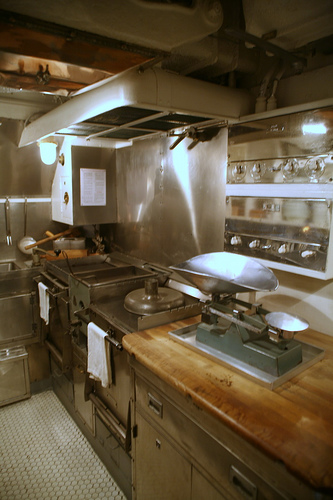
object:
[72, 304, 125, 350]
rack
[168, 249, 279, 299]
bed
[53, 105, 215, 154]
range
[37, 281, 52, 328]
towel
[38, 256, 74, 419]
stove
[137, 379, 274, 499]
drawer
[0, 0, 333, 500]
kitchen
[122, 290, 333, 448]
counter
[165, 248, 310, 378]
scale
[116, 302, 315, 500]
cabinet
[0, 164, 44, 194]
wall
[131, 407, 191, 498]
door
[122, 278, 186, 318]
lid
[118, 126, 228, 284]
back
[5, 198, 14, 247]
utensil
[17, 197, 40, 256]
utensil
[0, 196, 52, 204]
rack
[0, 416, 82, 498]
floor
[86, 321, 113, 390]
towel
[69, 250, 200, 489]
kitchen stove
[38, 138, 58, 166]
bulb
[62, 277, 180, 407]
appliances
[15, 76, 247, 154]
hood